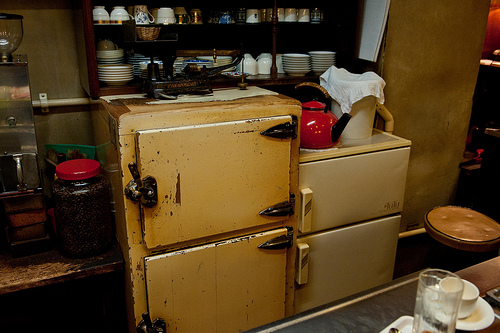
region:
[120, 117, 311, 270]
Tan fridge in a kitchen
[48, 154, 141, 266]
Jar on a counter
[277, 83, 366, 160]
Red teapot on a frige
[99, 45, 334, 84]
Dishes in a shelf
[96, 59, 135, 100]
Stack of white plates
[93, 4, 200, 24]
Teacups in a cupboard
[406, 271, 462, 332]
Glass on a counter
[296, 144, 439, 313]
Fridge in a kitchen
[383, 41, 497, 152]
Gray wall in a kitchen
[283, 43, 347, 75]
White bowels on a shelf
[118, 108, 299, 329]
a short yellow rusty refrigerator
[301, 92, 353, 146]
a red teapot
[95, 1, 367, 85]
a shelf that holds dishes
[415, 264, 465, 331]
a clear empty glass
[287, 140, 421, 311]
a short white fridge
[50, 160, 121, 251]
a jar full of beans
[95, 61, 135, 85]
a stack of plates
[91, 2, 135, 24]
two tea cups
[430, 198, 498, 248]
a brown seat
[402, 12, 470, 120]
a brown kitchen wall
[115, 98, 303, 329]
A dilapidated fridge.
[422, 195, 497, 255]
A stool.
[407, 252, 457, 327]
An empty glass.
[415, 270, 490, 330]
A tea cup on a saucer.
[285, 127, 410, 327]
A small fridge.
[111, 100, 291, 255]
A latch is on the freezer door.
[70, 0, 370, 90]
Two shelves full of cups and dishes.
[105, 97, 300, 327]
Rust is on the metal parts of the fridge.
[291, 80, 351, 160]
A red tea kettle.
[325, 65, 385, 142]
A container with a small towel over it.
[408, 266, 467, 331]
a clear drinking grass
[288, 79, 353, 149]
a red tea pot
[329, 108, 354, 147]
a black tea pot spout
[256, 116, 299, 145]
a black hinge on the refrigerator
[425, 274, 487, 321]
a white tea cup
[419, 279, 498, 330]
a white saucer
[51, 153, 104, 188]
a red jar lid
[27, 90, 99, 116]
a white pipe on the wall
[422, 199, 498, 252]
a kitchen stool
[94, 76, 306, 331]
vintage yellow ice box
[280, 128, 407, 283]
mini two door refrigerator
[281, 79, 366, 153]
red teakettle on refrigerator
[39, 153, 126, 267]
jar with red lid on counter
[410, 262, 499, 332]
cup and saucer on counter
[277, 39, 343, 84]
stack of bowls on shelf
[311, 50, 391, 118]
white dishcloth on container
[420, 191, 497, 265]
round brown vinyl stool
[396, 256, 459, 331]
tall, clear water glass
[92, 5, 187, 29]
gold rimmed coffee cups